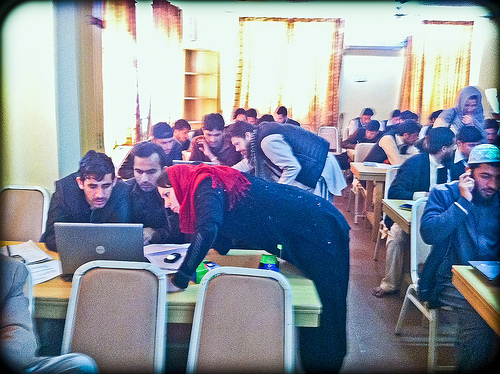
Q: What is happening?
A: People are learning.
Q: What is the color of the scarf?
A: Red.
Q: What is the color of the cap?
A: White.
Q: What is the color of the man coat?
A: Black.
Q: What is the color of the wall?
A: White.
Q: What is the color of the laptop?
A: Grey.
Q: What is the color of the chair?
A: Red and grey.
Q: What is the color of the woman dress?
A: Black.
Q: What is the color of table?
A: Green.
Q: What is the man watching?
A: Laptop.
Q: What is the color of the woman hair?
A: Black.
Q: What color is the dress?
A: Black.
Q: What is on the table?
A: Laptop.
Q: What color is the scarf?
A: Red.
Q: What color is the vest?
A: Black.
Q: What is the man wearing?
A: A vest.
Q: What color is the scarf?
A: Red.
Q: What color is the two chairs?
A: Brown.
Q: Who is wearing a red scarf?
A: A woman bending over.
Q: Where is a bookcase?
A: In the back of the room.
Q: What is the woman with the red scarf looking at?
A: A laptop.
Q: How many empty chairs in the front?
A: 2.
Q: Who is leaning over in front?
A: The woman in black.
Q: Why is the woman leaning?
A: To see the computer.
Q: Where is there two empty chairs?
A: The front left table.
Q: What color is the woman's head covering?
A: Red.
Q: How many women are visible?
A: 2.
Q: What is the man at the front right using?
A: A cell phone.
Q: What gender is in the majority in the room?
A: Male.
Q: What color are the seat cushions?
A: Tan.